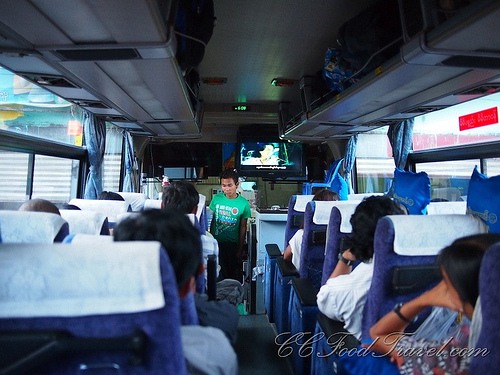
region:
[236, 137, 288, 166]
video in front of the vehicle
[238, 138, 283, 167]
screen in front of the vehicle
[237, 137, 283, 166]
TV in front of the vehicle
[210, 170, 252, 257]
person in a green shirt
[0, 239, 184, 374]
a blue seat with a white cloth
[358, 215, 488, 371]
a blue seat with a white cloth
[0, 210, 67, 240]
a blue seat with a white cloth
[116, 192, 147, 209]
a blue seat with a white cloth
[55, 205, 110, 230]
a blue seat with a white cloth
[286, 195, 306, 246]
a blue seat with a white cloth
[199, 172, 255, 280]
man at front of bus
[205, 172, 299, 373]
man is in aisle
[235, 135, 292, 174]
tv hangs in front of bus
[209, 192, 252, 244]
man wears green shirt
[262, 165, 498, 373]
bus seats are blue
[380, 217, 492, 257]
seat has white headrest cover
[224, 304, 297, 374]
aisle is narrow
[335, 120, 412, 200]
window has curtains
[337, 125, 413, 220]
curtains are blue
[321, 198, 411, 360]
man is sitting in bus seat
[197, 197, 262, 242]
the shirt is green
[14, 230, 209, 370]
the seat is blue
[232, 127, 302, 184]
the tv is on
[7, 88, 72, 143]
the window is clear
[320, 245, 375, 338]
the cloth is white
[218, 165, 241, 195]
the hair is black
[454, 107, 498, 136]
the color is red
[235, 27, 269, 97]
the ceiling is white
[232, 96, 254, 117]
the light is green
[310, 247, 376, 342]
the shirt is white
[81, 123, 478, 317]
there are people in the bus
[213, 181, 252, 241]
the man has a green top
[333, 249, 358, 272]
there is watch on his hand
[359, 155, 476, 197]
the windows are open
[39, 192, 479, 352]
there are 10 people in the bus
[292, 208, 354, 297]
the chairs are blue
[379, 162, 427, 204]
there are blue pillows on the window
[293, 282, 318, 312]
the armrest are black in color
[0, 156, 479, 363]
the photo is indoors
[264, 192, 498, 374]
Rows of seats on a bus.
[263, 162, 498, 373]
Row of seats with pillows.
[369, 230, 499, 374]
Woman sitting in a bus seat.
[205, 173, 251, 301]
Man standing in the aisle.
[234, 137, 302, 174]
Television screen.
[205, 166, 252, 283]
Person in a green shirt.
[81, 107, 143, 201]
Curtains hanging in the bus window.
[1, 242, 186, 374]
Back of a bus seat.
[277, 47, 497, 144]
Overhead luggage storage.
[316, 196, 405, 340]
Person in a white shirt sitting in a seat.